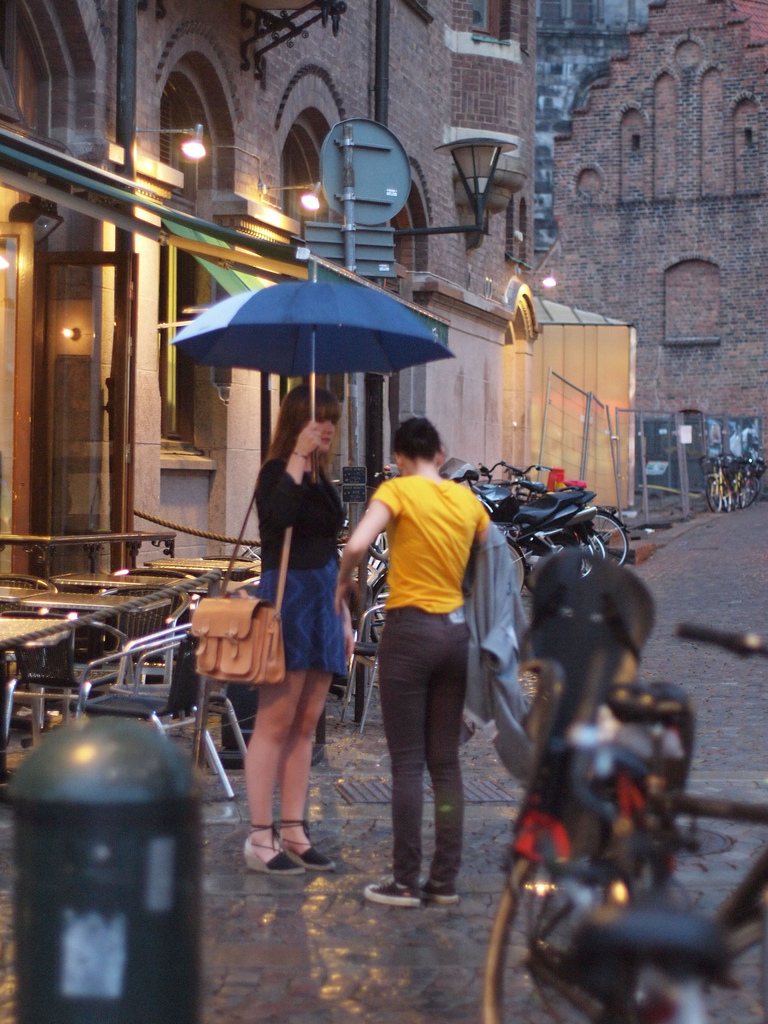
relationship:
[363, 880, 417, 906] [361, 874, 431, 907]
shoe on foot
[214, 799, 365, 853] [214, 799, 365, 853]
shoe on foot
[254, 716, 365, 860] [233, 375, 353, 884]
leg of girl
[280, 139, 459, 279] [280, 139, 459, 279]
sign on a post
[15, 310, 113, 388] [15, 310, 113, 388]
light on wall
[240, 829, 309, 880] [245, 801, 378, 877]
shoe on foot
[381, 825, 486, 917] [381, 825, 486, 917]
shoe on foot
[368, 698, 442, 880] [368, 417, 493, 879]
leg of person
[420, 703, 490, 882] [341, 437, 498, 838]
leg of person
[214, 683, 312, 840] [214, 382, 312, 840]
leg of person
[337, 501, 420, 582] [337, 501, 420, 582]
arm of person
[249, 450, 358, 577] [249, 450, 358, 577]
arm of person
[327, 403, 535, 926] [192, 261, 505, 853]
people holding umbrella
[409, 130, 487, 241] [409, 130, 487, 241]
light on pole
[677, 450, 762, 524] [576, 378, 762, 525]
cycles parked by fence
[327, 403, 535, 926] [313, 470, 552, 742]
people in shirt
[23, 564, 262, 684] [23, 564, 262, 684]
rope on bar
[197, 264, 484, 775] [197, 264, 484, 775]
couple under umbrella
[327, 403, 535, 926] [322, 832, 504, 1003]
people wearing shoes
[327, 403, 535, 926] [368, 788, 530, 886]
people wearing shoes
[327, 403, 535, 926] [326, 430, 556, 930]
people wearing shoes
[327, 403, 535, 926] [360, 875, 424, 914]
people wearing shoe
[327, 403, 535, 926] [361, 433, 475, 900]
people wearing pants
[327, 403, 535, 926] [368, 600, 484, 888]
people wearing pants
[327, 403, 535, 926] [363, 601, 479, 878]
people wearing pants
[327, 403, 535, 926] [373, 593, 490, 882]
people wearing pants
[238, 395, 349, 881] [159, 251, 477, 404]
girl under umbrella